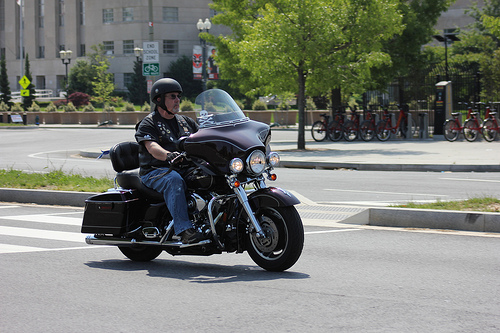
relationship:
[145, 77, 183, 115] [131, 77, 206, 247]
head of a person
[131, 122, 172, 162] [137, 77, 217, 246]
arm of a person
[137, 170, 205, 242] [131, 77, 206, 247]
leg of a person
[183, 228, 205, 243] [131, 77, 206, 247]
foot of a person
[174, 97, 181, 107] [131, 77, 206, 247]
nose of a person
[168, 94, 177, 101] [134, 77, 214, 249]
eye of a man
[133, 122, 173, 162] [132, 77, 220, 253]
arm of a person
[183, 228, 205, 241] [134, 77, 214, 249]
foot of a man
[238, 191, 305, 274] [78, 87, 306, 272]
wheel of a motorcycle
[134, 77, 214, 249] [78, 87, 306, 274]
man on motorcycle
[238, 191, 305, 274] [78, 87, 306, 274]
wheel of motorcycle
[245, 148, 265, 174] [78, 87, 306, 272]
light on motorcycle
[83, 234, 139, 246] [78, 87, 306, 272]
muffler on motorcycle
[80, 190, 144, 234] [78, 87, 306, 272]
carrying case on motorcycle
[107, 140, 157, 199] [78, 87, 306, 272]
seat on motorcycle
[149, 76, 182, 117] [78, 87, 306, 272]
helmet on motorcycle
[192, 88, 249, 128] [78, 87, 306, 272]
windshield on motorcycle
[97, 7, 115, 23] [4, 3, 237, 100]
window of building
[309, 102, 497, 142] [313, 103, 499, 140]
bicycles in rack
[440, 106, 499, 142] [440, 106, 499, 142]
bicycles in rack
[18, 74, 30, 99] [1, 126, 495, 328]
sign by road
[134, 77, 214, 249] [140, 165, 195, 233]
man wearing jeans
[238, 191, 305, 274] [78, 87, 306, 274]
wheel on motorcycle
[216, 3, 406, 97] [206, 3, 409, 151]
leaves on tree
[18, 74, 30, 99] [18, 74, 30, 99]
sign on sign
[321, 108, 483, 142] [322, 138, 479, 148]
bikes parked on sidewalk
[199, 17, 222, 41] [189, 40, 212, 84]
lights on pole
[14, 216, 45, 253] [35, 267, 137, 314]
lines on street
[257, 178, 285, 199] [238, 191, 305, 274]
fender over wheel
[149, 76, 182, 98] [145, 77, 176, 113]
helmet on head